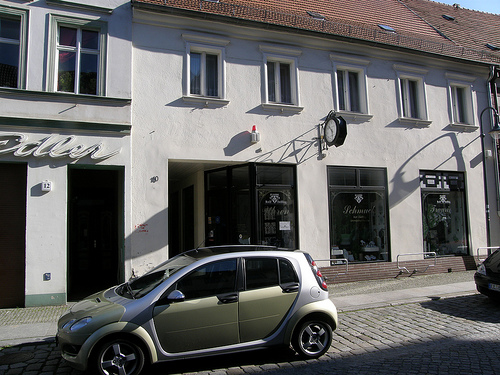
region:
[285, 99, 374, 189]
the clock is attched to the building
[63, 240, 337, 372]
the car is parked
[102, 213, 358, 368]
the car is four door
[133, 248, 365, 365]
the car is shiny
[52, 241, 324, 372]
the car is off green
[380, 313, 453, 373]
the road is cobblestone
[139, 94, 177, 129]
the bulding is white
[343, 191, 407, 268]
the windows have writing on them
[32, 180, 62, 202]
the number is 12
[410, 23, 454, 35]
the roof is shingled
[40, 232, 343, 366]
The car is light green.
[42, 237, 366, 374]
The car is small.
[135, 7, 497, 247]
The building is white.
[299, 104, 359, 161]
The building has a clock in front of it.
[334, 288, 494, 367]
The street has cobblestones.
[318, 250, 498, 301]
The building has bike racks in front of it.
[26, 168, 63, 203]
The number twelve is on the wall.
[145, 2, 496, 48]
The roof of building is brown.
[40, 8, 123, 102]
The window doesn't have curtains.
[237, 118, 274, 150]
Red light is on the wall.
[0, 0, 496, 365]
cars parked in front of buildings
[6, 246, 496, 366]
green and silver car on cobblestone street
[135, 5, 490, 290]
red roof over gray buildings with large store windows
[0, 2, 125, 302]
scripted sign in between windows and doorways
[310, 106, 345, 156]
white clock in black frame with dark hands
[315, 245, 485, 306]
silver railings on brick panel on grey sidewalk pavement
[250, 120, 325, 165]
shadow showing design on metal support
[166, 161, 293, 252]
dark window by side of recessed entryway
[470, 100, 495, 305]
curved black lamppost behind car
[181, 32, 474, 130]
row of divided windows with sills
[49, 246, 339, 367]
Car parked near curb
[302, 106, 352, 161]
Clock hanging from building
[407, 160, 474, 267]
large window on building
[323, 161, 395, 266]
Large window on building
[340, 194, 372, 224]
Writing on the window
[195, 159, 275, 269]
Doorway on the building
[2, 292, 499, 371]
Street made of brick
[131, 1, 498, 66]
Roof on the building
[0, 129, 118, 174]
Large letters on the building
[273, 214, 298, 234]
White sign on window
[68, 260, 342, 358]
A small green car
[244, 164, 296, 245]
A black glass window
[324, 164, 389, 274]
A black glass window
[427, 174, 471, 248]
A black glass window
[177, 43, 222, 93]
A black glass window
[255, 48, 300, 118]
A black glass window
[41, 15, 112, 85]
A black glass window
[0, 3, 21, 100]
A black glass window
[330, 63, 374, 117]
A black glass window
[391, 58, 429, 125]
A black glass window